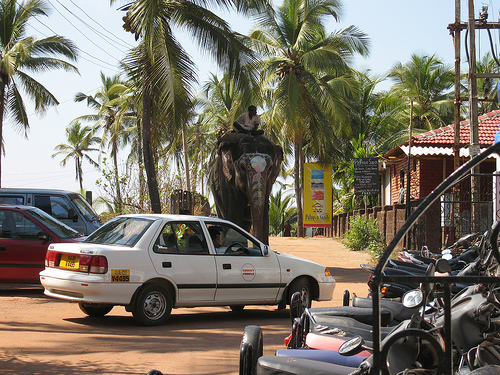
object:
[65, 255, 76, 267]
text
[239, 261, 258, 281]
symbol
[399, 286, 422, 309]
mirror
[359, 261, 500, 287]
motorcycle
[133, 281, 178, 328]
tire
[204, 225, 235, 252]
driver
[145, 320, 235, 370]
shadow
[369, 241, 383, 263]
tree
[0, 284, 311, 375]
ground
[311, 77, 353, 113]
leaves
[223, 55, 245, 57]
leaves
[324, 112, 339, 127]
leaves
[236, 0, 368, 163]
tree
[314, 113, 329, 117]
leaves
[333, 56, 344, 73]
leaves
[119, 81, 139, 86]
leaves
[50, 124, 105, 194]
palm tree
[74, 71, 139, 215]
palm tree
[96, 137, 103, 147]
leaves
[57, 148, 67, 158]
leaves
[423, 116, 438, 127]
leaves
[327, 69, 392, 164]
palm tree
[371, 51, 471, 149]
palm tree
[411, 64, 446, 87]
leaves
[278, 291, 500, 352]
bike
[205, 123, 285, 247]
elephant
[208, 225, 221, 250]
person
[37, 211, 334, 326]
car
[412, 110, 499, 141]
tile roof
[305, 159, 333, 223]
sign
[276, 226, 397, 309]
road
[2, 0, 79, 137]
palm trees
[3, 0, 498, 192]
sky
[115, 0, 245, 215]
palm trees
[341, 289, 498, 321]
motorbikes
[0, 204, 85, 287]
car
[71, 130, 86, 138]
leaves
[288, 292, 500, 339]
motorbikes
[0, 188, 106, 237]
car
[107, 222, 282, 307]
side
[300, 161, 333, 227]
banner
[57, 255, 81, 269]
license plate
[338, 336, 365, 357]
mirror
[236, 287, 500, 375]
bike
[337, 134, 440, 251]
wall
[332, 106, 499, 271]
building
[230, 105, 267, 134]
man